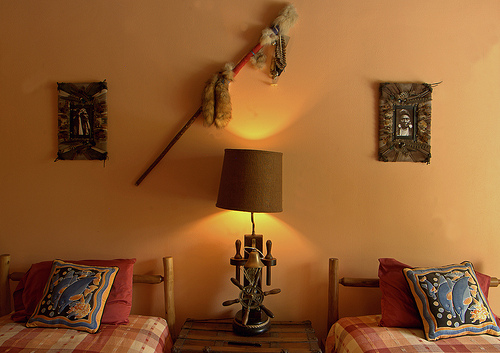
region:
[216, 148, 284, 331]
Lamp that is turned on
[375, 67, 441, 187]
Indian photography hanging on wall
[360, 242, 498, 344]
Two throw pillows on bed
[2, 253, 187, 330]
Wooden bed frame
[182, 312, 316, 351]
Wooden square end table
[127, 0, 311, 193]
Indian weapon with fur on it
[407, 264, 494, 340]
Dolphin design on the pillow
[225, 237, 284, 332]
Nautical themed lamp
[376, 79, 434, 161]
Frame covered in feathers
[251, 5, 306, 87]
Fur and feathers on pole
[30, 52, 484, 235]
pictures on the wall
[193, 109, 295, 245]
the lamp is brown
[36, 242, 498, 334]
pillows on the bed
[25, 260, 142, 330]
the pillow is red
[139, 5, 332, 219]
a stick on the wall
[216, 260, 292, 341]
the lamp has wheels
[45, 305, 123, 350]
the bed is checkered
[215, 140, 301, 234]
the lamp is turned on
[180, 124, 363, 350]
the lamp on the table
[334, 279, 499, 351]
the bed is narrow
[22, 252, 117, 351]
pillow on top of bed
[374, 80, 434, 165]
Native American artwork hanging on wall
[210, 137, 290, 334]
table lamp is on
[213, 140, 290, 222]
lamp shade is crooked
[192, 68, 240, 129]
fur tails on Native American Artwork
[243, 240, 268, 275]
bell on decorative lamp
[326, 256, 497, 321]
bed is made of wood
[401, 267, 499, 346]
pillow is orange, blue and black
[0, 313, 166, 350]
bedspread has plaid pattern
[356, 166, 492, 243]
wall is painted orange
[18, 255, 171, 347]
two pillows on the bed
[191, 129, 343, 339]
the lampshade is on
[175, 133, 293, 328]
the lampshade is brown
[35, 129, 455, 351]
lampshade on the table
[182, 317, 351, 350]
table in between the bed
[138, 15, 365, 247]
a stick with fur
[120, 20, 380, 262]
stick on the wall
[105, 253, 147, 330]
the pillow is red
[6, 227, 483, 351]
two narrow beds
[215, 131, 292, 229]
dark brown lamp shade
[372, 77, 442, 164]
photo of a person on the wall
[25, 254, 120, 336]
brown and orange pillow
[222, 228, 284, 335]
lamp that is turned on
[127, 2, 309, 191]
stick on the wall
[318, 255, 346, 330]
wooden bed post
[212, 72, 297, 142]
light from the lamp on the wall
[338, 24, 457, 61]
tan colored bedroom wall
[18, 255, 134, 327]
red pillow on a bed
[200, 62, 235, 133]
furs on a stick